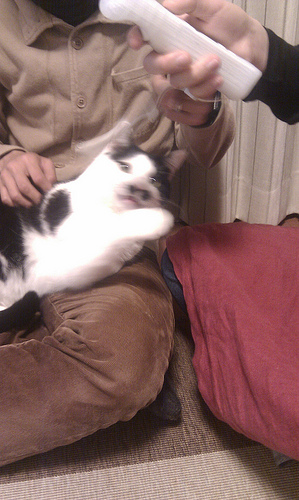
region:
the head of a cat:
[106, 128, 179, 213]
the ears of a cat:
[102, 110, 202, 167]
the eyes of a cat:
[115, 156, 161, 182]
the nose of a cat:
[124, 171, 145, 188]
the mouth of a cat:
[118, 189, 146, 204]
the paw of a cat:
[99, 210, 185, 249]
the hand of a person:
[11, 125, 60, 207]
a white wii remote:
[98, 10, 253, 116]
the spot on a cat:
[29, 188, 80, 229]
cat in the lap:
[0, 113, 169, 266]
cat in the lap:
[0, 123, 184, 304]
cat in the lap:
[7, 123, 179, 331]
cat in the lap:
[42, 125, 179, 286]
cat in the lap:
[69, 125, 198, 288]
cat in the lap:
[62, 122, 184, 268]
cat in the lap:
[65, 131, 174, 285]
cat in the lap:
[63, 128, 167, 285]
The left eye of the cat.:
[118, 162, 135, 175]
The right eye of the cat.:
[148, 175, 162, 185]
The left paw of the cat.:
[121, 209, 169, 240]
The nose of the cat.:
[127, 185, 148, 198]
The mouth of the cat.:
[119, 193, 137, 204]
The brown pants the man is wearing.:
[0, 262, 167, 459]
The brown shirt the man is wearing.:
[2, 0, 221, 190]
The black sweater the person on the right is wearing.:
[252, 21, 298, 120]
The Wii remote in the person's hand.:
[97, 0, 261, 104]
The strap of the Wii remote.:
[68, 100, 213, 158]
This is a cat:
[12, 121, 170, 304]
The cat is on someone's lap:
[8, 137, 186, 324]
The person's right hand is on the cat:
[2, 142, 70, 209]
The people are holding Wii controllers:
[90, 5, 271, 136]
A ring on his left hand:
[166, 89, 185, 116]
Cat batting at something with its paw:
[113, 191, 178, 244]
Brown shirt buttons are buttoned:
[62, 22, 95, 155]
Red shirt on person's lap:
[168, 217, 294, 449]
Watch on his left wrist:
[205, 86, 225, 135]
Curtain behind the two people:
[183, 100, 291, 222]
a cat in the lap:
[102, 145, 199, 300]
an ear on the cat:
[164, 149, 202, 181]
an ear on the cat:
[106, 106, 148, 167]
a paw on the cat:
[136, 201, 178, 241]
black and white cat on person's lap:
[0, 118, 190, 332]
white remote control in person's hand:
[95, 0, 265, 103]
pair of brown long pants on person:
[0, 243, 178, 470]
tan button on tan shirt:
[72, 91, 89, 110]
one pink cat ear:
[162, 143, 193, 181]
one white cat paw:
[138, 203, 178, 243]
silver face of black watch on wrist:
[206, 90, 223, 127]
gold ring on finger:
[174, 94, 187, 112]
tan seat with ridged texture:
[2, 325, 298, 499]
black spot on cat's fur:
[42, 185, 74, 240]